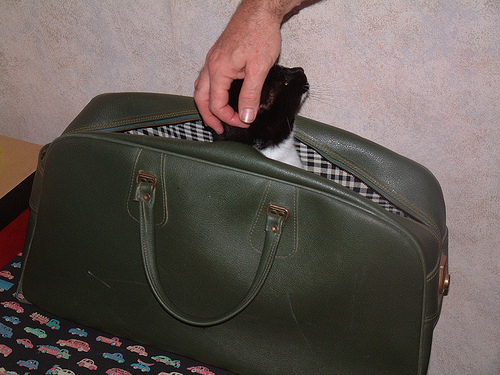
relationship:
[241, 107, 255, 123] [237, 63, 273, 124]
fingernail on thumb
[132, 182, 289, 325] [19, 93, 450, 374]
handle on bag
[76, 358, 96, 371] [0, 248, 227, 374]
car on cloth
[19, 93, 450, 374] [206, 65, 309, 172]
bag with a kitten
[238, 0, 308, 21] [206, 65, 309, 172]
arm touching kitten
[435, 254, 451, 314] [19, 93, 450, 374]
buckle on side of bag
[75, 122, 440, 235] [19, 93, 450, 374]
zipper on bag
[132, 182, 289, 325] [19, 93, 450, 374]
handle of bag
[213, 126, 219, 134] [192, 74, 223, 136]
nail on finger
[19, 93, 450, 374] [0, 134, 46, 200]
bag on table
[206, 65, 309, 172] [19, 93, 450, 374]
kitten in bag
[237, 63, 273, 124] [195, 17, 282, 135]
thumb of hand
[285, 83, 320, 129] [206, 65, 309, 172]
whiskers on kitten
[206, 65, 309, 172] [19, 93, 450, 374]
kitten in a bag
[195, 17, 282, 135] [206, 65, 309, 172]
hand on kitten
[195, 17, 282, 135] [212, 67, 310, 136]
hand on head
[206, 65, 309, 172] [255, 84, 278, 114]
kitten has eyes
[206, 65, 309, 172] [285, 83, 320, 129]
kitten has whiskers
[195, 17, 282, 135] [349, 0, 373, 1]
hand with body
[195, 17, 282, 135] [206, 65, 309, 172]
hand petting kitten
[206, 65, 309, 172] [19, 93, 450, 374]
kitten inside of a bag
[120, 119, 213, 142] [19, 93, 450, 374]
checkerboard lining in a purse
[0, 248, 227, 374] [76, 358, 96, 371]
cloth with car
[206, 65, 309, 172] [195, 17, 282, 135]
kitten with mans hand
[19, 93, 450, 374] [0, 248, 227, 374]
bag on cloth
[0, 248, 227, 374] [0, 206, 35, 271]
cloth has border